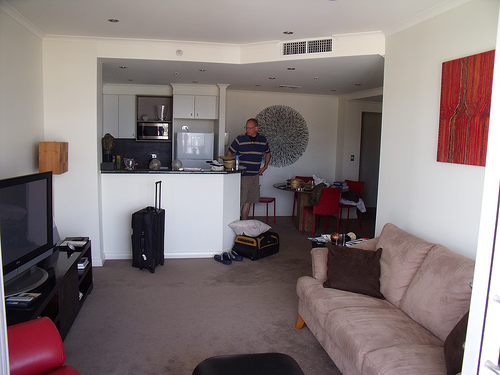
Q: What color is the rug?
A: Cream.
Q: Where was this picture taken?
A: Inside a house.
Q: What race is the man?
A: White.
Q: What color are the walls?
A: White.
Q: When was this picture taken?
A: During the day.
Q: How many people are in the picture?
A: One.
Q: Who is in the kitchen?
A: A man.